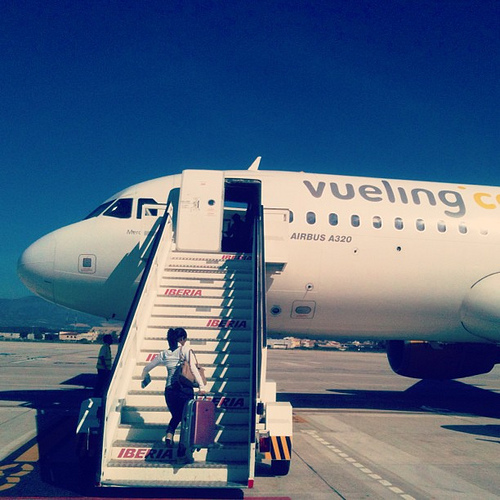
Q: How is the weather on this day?
A: It is clear.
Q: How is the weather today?
A: It is clear.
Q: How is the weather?
A: It is clear.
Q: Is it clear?
A: Yes, it is clear.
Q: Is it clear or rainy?
A: It is clear.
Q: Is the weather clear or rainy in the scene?
A: It is clear.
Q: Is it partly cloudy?
A: No, it is clear.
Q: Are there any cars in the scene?
A: No, there are no cars.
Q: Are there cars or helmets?
A: No, there are no cars or helmets.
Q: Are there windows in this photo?
A: Yes, there is a window.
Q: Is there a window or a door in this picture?
A: Yes, there is a window.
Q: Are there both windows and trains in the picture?
A: No, there is a window but no trains.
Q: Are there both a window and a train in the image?
A: No, there is a window but no trains.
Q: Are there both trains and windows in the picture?
A: No, there is a window but no trains.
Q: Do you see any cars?
A: No, there are no cars.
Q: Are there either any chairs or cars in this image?
A: No, there are no cars or chairs.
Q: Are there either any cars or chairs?
A: No, there are no cars or chairs.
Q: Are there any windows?
A: Yes, there is a window.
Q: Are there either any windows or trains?
A: Yes, there is a window.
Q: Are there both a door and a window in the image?
A: Yes, there are both a window and a door.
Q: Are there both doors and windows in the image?
A: Yes, there are both a window and a door.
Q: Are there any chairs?
A: No, there are no chairs.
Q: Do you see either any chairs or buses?
A: No, there are no chairs or buses.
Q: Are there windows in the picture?
A: Yes, there is a window.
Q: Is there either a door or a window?
A: Yes, there is a window.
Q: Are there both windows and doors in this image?
A: Yes, there are both a window and a door.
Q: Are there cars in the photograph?
A: No, there are no cars.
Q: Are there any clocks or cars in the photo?
A: No, there are no cars or clocks.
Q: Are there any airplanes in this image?
A: Yes, there is an airplane.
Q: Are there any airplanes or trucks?
A: Yes, there is an airplane.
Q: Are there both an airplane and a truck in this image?
A: No, there is an airplane but no trucks.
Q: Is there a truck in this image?
A: No, there are no trucks.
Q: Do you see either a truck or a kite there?
A: No, there are no trucks or kites.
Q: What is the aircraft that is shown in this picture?
A: The aircraft is an airplane.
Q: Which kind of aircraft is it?
A: The aircraft is an airplane.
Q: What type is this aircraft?
A: This is an airplane.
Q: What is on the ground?
A: The airplane is on the ground.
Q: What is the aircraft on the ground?
A: The aircraft is an airplane.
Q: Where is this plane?
A: The plane is on the ground.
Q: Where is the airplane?
A: The plane is on the ground.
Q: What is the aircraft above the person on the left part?
A: The aircraft is an airplane.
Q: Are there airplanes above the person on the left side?
A: Yes, there is an airplane above the person.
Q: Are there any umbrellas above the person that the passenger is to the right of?
A: No, there is an airplane above the person.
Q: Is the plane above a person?
A: Yes, the plane is above a person.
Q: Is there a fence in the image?
A: No, there are no fences.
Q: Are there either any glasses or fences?
A: No, there are no fences or glasses.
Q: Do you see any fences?
A: No, there are no fences.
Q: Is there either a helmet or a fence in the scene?
A: No, there are no fences or helmets.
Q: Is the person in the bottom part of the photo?
A: Yes, the person is in the bottom of the image.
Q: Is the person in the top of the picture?
A: No, the person is in the bottom of the image.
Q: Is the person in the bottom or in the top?
A: The person is in the bottom of the image.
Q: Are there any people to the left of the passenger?
A: Yes, there is a person to the left of the passenger.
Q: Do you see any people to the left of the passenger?
A: Yes, there is a person to the left of the passenger.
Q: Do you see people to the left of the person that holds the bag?
A: Yes, there is a person to the left of the passenger.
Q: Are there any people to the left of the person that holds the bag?
A: Yes, there is a person to the left of the passenger.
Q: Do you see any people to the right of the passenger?
A: No, the person is to the left of the passenger.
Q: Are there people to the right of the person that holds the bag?
A: No, the person is to the left of the passenger.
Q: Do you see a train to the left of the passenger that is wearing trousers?
A: No, there is a person to the left of the passenger.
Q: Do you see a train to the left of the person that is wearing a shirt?
A: No, there is a person to the left of the passenger.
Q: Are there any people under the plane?
A: Yes, there is a person under the plane.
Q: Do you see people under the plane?
A: Yes, there is a person under the plane.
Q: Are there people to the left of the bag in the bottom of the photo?
A: Yes, there is a person to the left of the bag.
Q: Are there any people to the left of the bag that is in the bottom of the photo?
A: Yes, there is a person to the left of the bag.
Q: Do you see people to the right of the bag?
A: No, the person is to the left of the bag.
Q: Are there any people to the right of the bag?
A: No, the person is to the left of the bag.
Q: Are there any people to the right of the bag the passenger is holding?
A: No, the person is to the left of the bag.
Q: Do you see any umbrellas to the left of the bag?
A: No, there is a person to the left of the bag.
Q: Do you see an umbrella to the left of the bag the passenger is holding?
A: No, there is a person to the left of the bag.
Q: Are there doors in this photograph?
A: Yes, there is a door.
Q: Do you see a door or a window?
A: Yes, there is a door.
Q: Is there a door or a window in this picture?
A: Yes, there is a door.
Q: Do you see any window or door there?
A: Yes, there is a door.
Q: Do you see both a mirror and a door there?
A: No, there is a door but no mirrors.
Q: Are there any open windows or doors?
A: Yes, there is an open door.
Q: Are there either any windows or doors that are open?
A: Yes, the door is open.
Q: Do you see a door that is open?
A: Yes, there is an open door.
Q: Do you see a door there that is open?
A: Yes, there is a door that is open.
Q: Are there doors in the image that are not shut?
A: Yes, there is a open door.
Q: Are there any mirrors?
A: No, there are no mirrors.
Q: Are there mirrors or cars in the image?
A: No, there are no mirrors or cars.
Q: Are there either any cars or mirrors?
A: No, there are no mirrors or cars.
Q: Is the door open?
A: Yes, the door is open.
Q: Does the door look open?
A: Yes, the door is open.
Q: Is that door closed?
A: No, the door is open.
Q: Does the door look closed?
A: No, the door is open.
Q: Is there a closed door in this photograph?
A: No, there is a door but it is open.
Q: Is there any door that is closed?
A: No, there is a door but it is open.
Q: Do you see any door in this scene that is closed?
A: No, there is a door but it is open.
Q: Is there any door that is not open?
A: No, there is a door but it is open.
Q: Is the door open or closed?
A: The door is open.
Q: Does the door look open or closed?
A: The door is open.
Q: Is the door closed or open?
A: The door is open.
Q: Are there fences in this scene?
A: No, there are no fences.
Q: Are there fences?
A: No, there are no fences.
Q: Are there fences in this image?
A: No, there are no fences.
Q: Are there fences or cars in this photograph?
A: No, there are no fences or cars.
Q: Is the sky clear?
A: Yes, the sky is clear.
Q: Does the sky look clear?
A: Yes, the sky is clear.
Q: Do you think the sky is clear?
A: Yes, the sky is clear.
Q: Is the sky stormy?
A: No, the sky is clear.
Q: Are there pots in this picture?
A: No, there are no pots.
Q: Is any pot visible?
A: No, there are no pots.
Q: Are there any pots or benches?
A: No, there are no pots or benches.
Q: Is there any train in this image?
A: No, there are no trains.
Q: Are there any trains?
A: No, there are no trains.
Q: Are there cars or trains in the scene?
A: No, there are no trains or cars.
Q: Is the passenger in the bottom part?
A: Yes, the passenger is in the bottom of the image.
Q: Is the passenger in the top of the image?
A: No, the passenger is in the bottom of the image.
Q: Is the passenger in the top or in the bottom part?
A: The passenger is in the bottom of the image.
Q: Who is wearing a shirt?
A: The passenger is wearing a shirt.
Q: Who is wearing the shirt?
A: The passenger is wearing a shirt.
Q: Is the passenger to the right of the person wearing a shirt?
A: Yes, the passenger is wearing a shirt.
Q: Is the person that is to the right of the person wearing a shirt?
A: Yes, the passenger is wearing a shirt.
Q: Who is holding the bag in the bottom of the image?
A: The passenger is holding the bag.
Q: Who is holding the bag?
A: The passenger is holding the bag.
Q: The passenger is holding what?
A: The passenger is holding the bag.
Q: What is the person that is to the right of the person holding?
A: The passenger is holding the bag.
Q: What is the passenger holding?
A: The passenger is holding the bag.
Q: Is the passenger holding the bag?
A: Yes, the passenger is holding the bag.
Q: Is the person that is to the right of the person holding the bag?
A: Yes, the passenger is holding the bag.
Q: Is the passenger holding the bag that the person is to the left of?
A: Yes, the passenger is holding the bag.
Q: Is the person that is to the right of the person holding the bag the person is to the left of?
A: Yes, the passenger is holding the bag.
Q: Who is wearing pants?
A: The passenger is wearing pants.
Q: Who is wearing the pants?
A: The passenger is wearing pants.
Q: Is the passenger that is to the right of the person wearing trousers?
A: Yes, the passenger is wearing trousers.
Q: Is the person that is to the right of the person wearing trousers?
A: Yes, the passenger is wearing trousers.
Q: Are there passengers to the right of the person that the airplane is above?
A: Yes, there is a passenger to the right of the person.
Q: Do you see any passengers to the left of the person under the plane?
A: No, the passenger is to the right of the person.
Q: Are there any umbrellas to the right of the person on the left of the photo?
A: No, there is a passenger to the right of the person.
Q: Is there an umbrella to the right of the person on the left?
A: No, there is a passenger to the right of the person.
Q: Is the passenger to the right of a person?
A: Yes, the passenger is to the right of a person.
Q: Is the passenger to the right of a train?
A: No, the passenger is to the right of a person.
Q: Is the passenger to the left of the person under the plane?
A: No, the passenger is to the right of the person.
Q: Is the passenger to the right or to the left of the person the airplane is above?
A: The passenger is to the right of the person.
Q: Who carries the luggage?
A: The passenger carries the luggage.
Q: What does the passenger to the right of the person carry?
A: The passenger carries luggage.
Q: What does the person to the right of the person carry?
A: The passenger carries luggage.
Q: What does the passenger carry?
A: The passenger carries luggage.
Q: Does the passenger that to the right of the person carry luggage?
A: Yes, the passenger carries luggage.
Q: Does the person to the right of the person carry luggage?
A: Yes, the passenger carries luggage.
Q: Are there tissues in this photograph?
A: No, there are no tissues.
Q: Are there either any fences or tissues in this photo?
A: No, there are no tissues or fences.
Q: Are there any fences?
A: No, there are no fences.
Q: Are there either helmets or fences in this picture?
A: No, there are no fences or helmets.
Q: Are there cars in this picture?
A: No, there are no cars.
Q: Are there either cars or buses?
A: No, there are no cars or buses.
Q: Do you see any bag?
A: Yes, there is a bag.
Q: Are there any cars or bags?
A: Yes, there is a bag.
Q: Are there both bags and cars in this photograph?
A: No, there is a bag but no cars.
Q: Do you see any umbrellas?
A: No, there are no umbrellas.